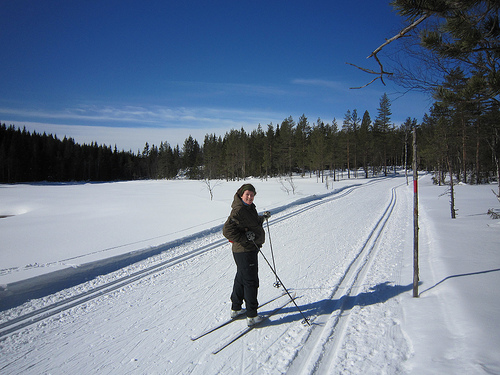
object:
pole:
[412, 127, 419, 298]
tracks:
[0, 177, 396, 338]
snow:
[0, 168, 500, 375]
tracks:
[282, 180, 408, 375]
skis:
[190, 288, 289, 342]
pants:
[230, 250, 260, 318]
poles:
[252, 239, 310, 326]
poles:
[266, 218, 279, 282]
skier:
[222, 182, 271, 328]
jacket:
[222, 193, 266, 254]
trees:
[202, 133, 217, 180]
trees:
[112, 142, 119, 181]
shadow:
[251, 279, 423, 328]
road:
[1, 171, 429, 375]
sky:
[0, 0, 498, 156]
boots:
[246, 314, 267, 327]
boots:
[229, 308, 247, 319]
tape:
[413, 179, 419, 192]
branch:
[347, 74, 382, 91]